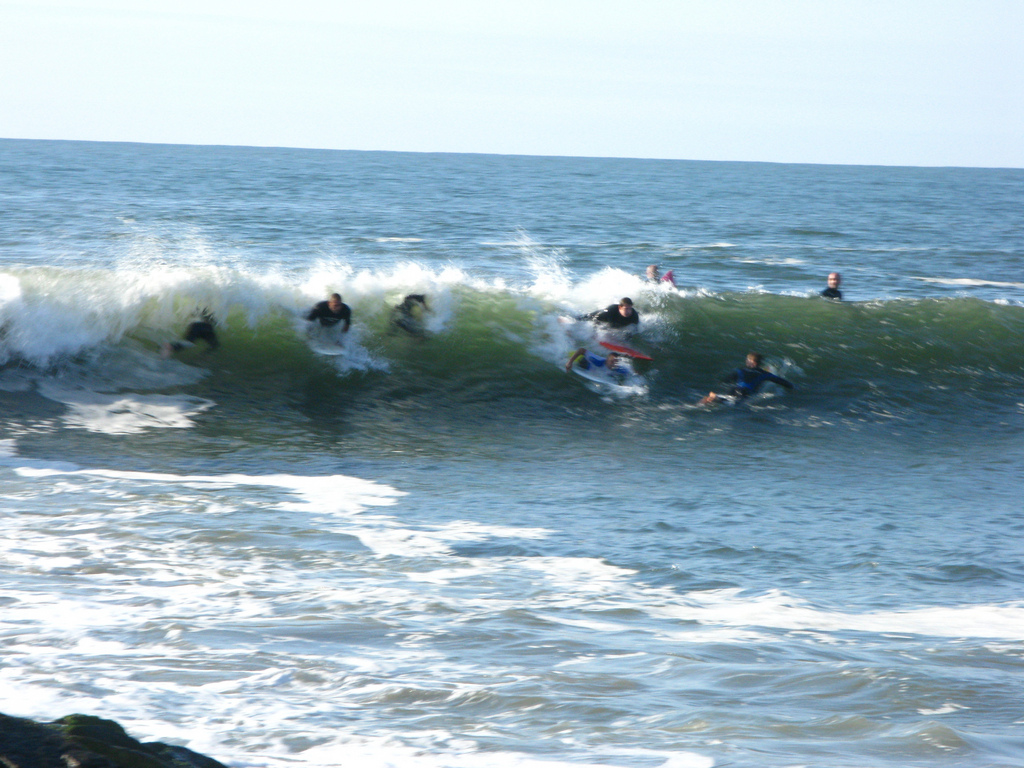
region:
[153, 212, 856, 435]
A group of people surfing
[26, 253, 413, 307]
The white splash from the wave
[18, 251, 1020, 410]
A wave with white foam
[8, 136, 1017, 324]
The portion of the ocean behind the surfers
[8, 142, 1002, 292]
A body of water behind the surfers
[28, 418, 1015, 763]
The area of water in front the surfers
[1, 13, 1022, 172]
A very clear sky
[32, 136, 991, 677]
this is the ocean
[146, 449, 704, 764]
these are waves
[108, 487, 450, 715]
the waves are white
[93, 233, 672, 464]
the waves are small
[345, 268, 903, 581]
the ocean is green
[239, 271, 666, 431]
the people are surfing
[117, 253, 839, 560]
the surfers are riding the wave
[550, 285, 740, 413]
the person is paddling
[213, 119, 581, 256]
the horizon is white and gray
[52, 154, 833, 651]
this is an ocean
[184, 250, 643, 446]
the wave is short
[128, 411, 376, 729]
the water is green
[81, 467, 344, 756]
the water is white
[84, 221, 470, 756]
the breakers are small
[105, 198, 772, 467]
these are surfers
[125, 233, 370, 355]
the sea foam is white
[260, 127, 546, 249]
the ocean is blue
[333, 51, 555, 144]
the sky is white and blue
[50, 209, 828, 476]
Waves in the water.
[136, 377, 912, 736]
White waves in the water.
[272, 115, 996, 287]
line of the sky.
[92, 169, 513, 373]
Spray from the waves.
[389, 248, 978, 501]
Green water.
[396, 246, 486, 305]
the foams of a wave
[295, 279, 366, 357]
a man on a surfboard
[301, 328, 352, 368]
a surfboard that is white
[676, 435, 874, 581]
the ocean that is still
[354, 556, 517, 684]
a bunch of ocean waves that are white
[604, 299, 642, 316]
the head of a person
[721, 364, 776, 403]
a wetsuit that is black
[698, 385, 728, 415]
the feet of a person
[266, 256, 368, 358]
person surfing in blue ocean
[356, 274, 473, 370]
person surfing in blue oceanperson surfing in blue ocean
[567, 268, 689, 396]
person surfing in blue ocean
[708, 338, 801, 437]
person surfing in blue ocean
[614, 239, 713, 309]
person surfing in blue ocean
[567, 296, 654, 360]
man is riding a surfboard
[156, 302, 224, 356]
man is lost in the wave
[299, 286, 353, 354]
surfer is riding surfboard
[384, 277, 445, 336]
surfer is lost in the wave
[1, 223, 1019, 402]
wave is crashing into the water